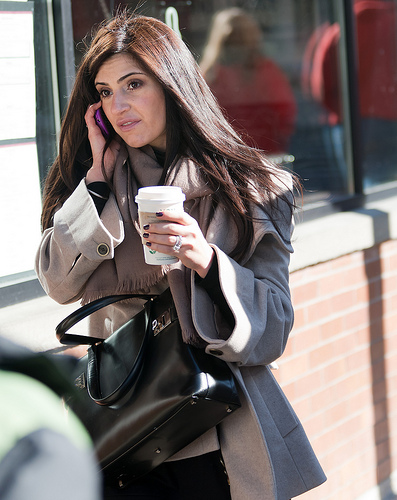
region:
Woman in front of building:
[36, 13, 328, 498]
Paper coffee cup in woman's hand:
[133, 184, 187, 266]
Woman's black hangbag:
[56, 285, 244, 473]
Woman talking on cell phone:
[74, 15, 227, 161]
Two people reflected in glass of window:
[200, 0, 393, 183]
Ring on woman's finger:
[172, 231, 183, 254]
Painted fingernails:
[140, 203, 164, 251]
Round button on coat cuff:
[97, 238, 109, 260]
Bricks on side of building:
[268, 247, 396, 498]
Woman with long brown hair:
[39, 0, 300, 269]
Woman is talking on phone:
[75, 24, 199, 154]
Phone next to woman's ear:
[77, 102, 122, 158]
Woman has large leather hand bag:
[49, 293, 246, 476]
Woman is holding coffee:
[128, 182, 203, 267]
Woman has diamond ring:
[170, 236, 187, 252]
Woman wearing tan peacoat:
[62, 121, 326, 499]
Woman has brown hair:
[64, 18, 259, 244]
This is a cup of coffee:
[128, 182, 193, 268]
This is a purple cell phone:
[89, 104, 115, 139]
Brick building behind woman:
[255, 252, 393, 498]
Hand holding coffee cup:
[137, 182, 182, 265]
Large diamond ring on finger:
[169, 233, 187, 252]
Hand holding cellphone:
[80, 104, 121, 165]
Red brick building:
[275, 246, 395, 496]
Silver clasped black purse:
[52, 290, 236, 494]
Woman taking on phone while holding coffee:
[34, 20, 326, 499]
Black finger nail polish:
[142, 223, 152, 246]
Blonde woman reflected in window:
[199, 4, 292, 149]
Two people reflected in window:
[191, 0, 395, 197]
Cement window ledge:
[287, 201, 395, 271]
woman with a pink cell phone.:
[46, 13, 342, 453]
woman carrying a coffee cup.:
[26, 11, 348, 333]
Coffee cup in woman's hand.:
[104, 141, 208, 257]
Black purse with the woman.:
[51, 276, 352, 494]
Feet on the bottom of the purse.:
[137, 382, 266, 452]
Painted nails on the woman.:
[113, 201, 190, 259]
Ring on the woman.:
[158, 210, 214, 282]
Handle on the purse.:
[51, 275, 188, 417]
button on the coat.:
[70, 186, 132, 296]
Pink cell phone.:
[58, 68, 144, 188]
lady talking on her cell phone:
[32, 12, 331, 496]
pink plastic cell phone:
[85, 105, 117, 142]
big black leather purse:
[49, 280, 252, 496]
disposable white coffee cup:
[131, 180, 185, 269]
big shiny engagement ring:
[163, 231, 188, 254]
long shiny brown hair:
[35, 8, 315, 260]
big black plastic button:
[93, 238, 111, 258]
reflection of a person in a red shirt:
[189, 0, 296, 166]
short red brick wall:
[2, 192, 395, 498]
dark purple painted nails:
[141, 204, 164, 251]